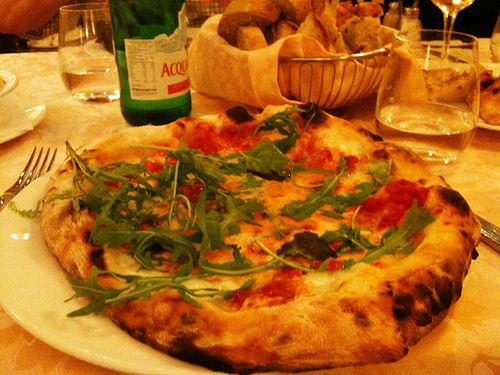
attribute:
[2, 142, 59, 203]
fork — silver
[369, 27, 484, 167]
cup — glass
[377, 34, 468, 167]
cup — glass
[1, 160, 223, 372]
plate — white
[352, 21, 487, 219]
cup — glass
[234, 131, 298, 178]
lettuce — green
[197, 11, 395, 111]
metal basket — gray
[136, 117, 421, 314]
tomatoes — sliced, red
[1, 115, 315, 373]
dinner plate — white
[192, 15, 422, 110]
basket — metal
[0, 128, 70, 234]
fork — gray, metal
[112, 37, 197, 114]
label — white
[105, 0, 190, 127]
bottle — green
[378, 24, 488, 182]
glass — clear, round, short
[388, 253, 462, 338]
spot — brown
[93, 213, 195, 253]
lettuce — green